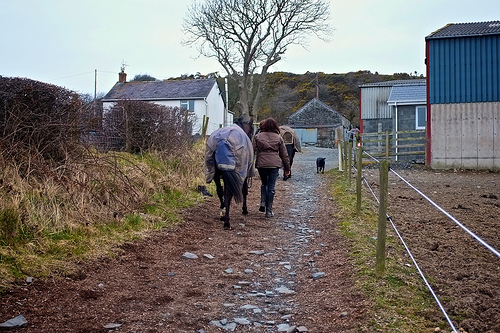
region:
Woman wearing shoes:
[257, 200, 277, 217]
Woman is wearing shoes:
[257, 201, 279, 223]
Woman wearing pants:
[256, 163, 279, 205]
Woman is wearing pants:
[254, 162, 279, 207]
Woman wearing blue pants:
[255, 163, 277, 200]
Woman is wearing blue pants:
[252, 162, 283, 192]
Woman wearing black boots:
[255, 180, 276, 220]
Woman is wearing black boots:
[256, 181, 279, 216]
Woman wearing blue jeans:
[253, 162, 281, 193]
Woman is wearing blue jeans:
[253, 161, 277, 194]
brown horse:
[209, 118, 255, 221]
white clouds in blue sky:
[320, 43, 356, 63]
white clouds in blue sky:
[386, 13, 405, 47]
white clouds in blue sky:
[18, 15, 41, 41]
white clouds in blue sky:
[43, 15, 92, 57]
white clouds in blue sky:
[72, 21, 145, 60]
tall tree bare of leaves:
[220, 11, 315, 60]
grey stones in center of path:
[231, 267, 257, 329]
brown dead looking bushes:
[9, 87, 79, 134]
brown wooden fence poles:
[376, 158, 398, 236]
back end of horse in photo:
[204, 126, 254, 209]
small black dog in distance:
[312, 138, 329, 185]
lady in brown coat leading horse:
[252, 118, 309, 226]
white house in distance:
[116, 66, 225, 120]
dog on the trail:
[312, 155, 323, 171]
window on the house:
[180, 101, 196, 111]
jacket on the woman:
[256, 132, 283, 164]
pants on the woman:
[260, 167, 273, 205]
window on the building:
[413, 106, 424, 127]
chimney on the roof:
[115, 70, 130, 80]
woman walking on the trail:
[252, 115, 292, 216]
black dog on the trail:
[307, 151, 329, 171]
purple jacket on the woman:
[248, 132, 284, 165]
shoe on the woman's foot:
[253, 205, 265, 211]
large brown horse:
[187, 106, 255, 233]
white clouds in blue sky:
[351, 15, 402, 50]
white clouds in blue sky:
[320, 20, 390, 56]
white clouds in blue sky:
[35, 7, 120, 37]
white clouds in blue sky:
[105, 15, 165, 50]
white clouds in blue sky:
[17, 5, 82, 47]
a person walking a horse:
[189, 97, 294, 227]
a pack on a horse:
[201, 105, 256, 232]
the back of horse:
[186, 120, 253, 230]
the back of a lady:
[244, 113, 288, 219]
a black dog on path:
[307, 148, 336, 175]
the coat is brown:
[254, 105, 293, 179]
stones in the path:
[251, 184, 327, 319]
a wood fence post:
[360, 153, 403, 296]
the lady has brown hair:
[251, 108, 292, 218]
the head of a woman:
[260, 116, 284, 136]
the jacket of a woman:
[249, 132, 292, 172]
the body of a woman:
[249, 128, 280, 170]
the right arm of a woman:
[273, 136, 293, 168]